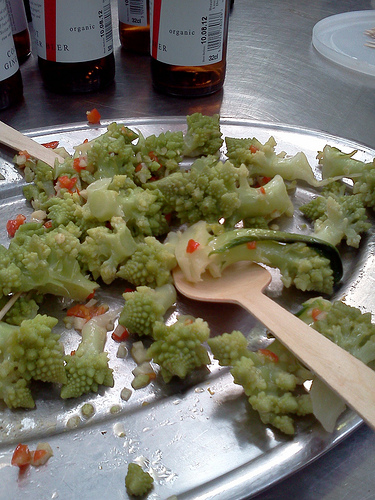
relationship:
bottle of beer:
[0, 9, 225, 98] [2, 3, 225, 112]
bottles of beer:
[0, 9, 225, 98] [2, 3, 225, 112]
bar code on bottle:
[97, 8, 222, 67] [147, 1, 226, 96]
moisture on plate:
[96, 370, 259, 496] [2, 119, 373, 497]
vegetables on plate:
[2, 119, 373, 497] [2, 119, 373, 497]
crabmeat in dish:
[1, 111, 371, 443] [6, 114, 373, 433]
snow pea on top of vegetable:
[205, 220, 345, 295] [2, 119, 373, 497]